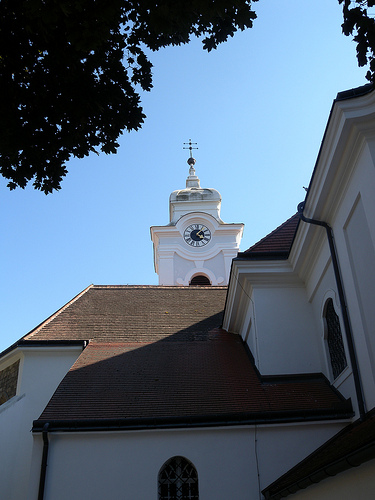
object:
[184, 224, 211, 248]
clock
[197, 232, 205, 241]
clock hands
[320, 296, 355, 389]
window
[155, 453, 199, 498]
white window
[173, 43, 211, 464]
grating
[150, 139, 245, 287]
steeple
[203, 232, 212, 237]
numbers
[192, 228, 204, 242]
center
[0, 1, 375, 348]
sky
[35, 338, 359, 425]
roof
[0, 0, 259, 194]
tree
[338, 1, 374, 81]
branch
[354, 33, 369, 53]
leaves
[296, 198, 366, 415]
drain pipe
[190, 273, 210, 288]
church window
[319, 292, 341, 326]
rounded top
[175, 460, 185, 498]
bars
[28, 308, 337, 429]
shadow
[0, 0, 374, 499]
scene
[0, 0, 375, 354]
sky and tree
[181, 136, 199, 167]
weather vane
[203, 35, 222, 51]
leaf